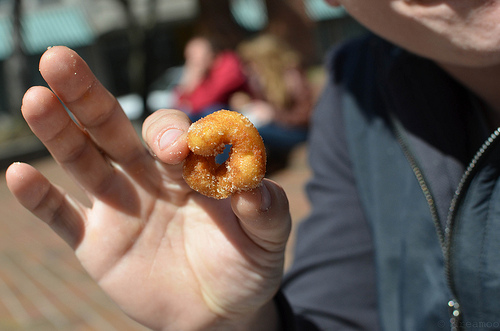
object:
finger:
[140, 109, 190, 164]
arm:
[276, 101, 389, 330]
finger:
[18, 85, 111, 193]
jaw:
[411, 30, 499, 69]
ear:
[318, 1, 343, 12]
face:
[325, 0, 499, 69]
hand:
[4, 44, 291, 330]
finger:
[4, 161, 86, 248]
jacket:
[275, 33, 499, 330]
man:
[5, 1, 499, 330]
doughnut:
[182, 108, 267, 202]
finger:
[40, 43, 142, 165]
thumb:
[225, 175, 297, 248]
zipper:
[440, 129, 500, 330]